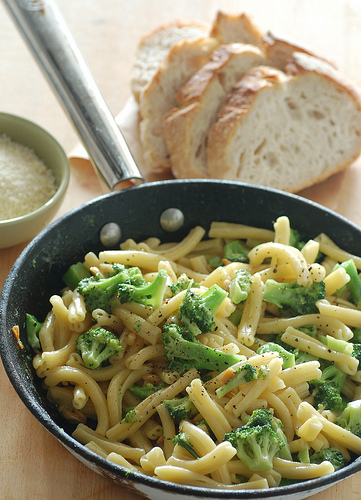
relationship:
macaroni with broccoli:
[32, 215, 361, 491] [22, 231, 360, 472]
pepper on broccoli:
[42, 246, 341, 461] [22, 231, 360, 472]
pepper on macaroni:
[42, 246, 341, 461] [32, 215, 361, 491]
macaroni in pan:
[32, 215, 361, 491] [4, 2, 361, 499]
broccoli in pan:
[22, 231, 360, 472] [4, 2, 361, 499]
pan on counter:
[4, 2, 361, 499] [2, 152, 360, 496]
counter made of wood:
[2, 152, 360, 496] [13, 157, 360, 500]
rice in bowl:
[1, 134, 60, 224] [2, 110, 72, 250]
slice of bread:
[205, 56, 359, 195] [122, 11, 360, 184]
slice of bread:
[164, 43, 300, 180] [122, 11, 360, 184]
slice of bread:
[129, 12, 259, 178] [122, 11, 360, 184]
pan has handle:
[4, 2, 361, 499] [6, 2, 145, 190]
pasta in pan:
[32, 215, 361, 491] [4, 2, 361, 499]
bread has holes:
[122, 11, 360, 184] [233, 146, 250, 178]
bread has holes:
[122, 11, 360, 184] [281, 96, 332, 123]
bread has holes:
[122, 11, 360, 184] [264, 140, 308, 172]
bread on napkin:
[122, 11, 360, 184] [61, 92, 144, 165]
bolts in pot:
[95, 202, 185, 249] [0, 178, 357, 492]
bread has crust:
[122, 11, 360, 184] [123, 10, 358, 195]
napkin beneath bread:
[61, 92, 144, 165] [122, 11, 360, 184]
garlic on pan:
[8, 323, 24, 351] [4, 2, 361, 499]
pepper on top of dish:
[42, 246, 341, 461] [24, 214, 359, 495]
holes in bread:
[233, 146, 250, 178] [122, 11, 360, 184]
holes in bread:
[281, 96, 332, 123] [122, 11, 360, 184]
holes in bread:
[264, 140, 308, 172] [122, 11, 360, 184]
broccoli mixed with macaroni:
[22, 231, 360, 472] [32, 215, 361, 491]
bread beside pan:
[122, 11, 360, 184] [4, 2, 361, 499]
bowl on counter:
[2, 110, 72, 250] [2, 152, 360, 496]